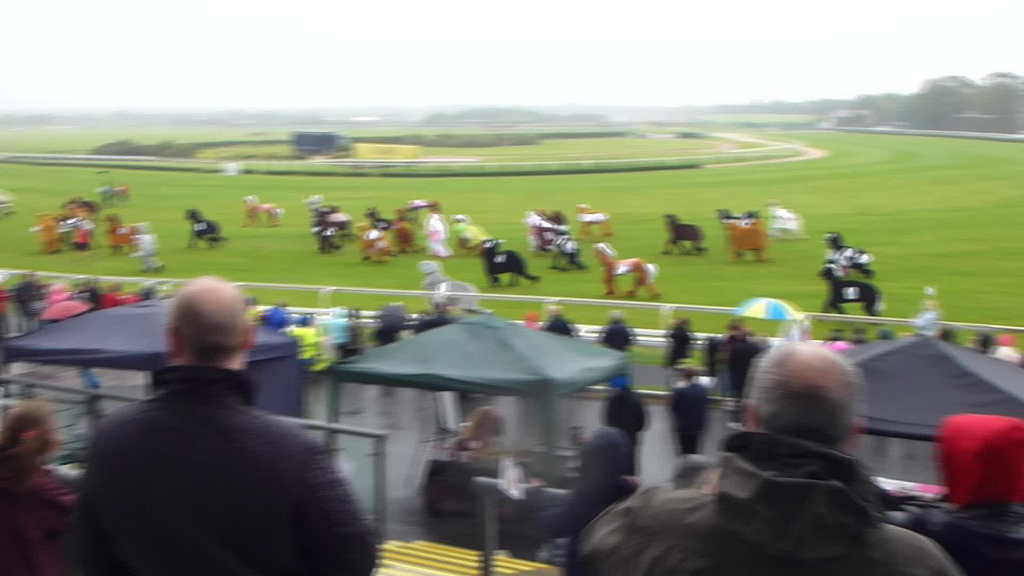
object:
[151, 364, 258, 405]
collar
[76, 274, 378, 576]
man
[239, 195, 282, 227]
horse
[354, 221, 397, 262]
horse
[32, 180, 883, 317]
horses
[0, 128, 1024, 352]
grass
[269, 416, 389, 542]
rail